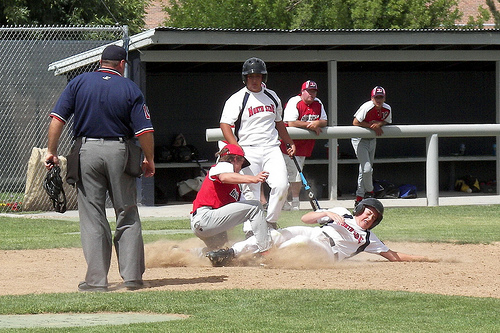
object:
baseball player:
[204, 198, 401, 267]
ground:
[0, 189, 499, 331]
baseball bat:
[281, 139, 320, 212]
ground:
[422, 125, 444, 168]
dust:
[129, 238, 349, 278]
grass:
[272, 293, 439, 331]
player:
[350, 86, 393, 208]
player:
[281, 79, 328, 210]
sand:
[366, 248, 487, 316]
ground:
[347, 189, 362, 215]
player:
[189, 142, 287, 266]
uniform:
[187, 142, 265, 267]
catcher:
[190, 142, 282, 268]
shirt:
[188, 161, 243, 212]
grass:
[1, 203, 498, 331]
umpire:
[42, 44, 156, 290]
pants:
[75, 137, 145, 287]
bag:
[390, 183, 418, 200]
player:
[218, 57, 298, 246]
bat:
[282, 141, 321, 211]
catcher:
[190, 142, 279, 262]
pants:
[191, 200, 272, 250]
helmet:
[353, 197, 385, 229]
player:
[210, 196, 435, 265]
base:
[266, 254, 316, 267]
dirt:
[1, 235, 498, 331]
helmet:
[242, 57, 268, 85]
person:
[219, 84, 296, 228]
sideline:
[204, 157, 496, 250]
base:
[203, 277, 329, 331]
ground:
[380, 181, 470, 238]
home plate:
[164, 247, 217, 269]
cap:
[101, 45, 132, 66]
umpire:
[43, 44, 156, 295]